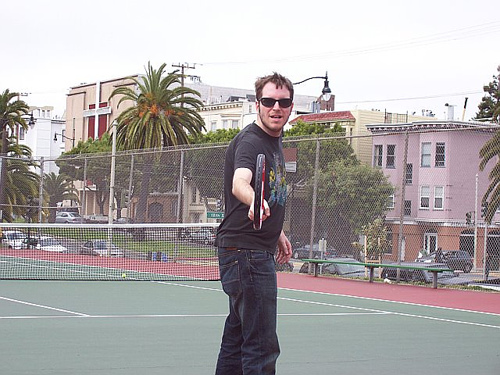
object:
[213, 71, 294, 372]
man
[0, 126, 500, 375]
court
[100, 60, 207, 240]
palm tree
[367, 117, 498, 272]
building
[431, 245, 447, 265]
person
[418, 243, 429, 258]
person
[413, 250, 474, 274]
car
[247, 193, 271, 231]
hand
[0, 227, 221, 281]
net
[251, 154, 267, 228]
racket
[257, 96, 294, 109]
sunglasses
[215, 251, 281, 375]
jean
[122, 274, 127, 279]
ball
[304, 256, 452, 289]
bench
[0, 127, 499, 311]
fence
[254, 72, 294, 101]
hair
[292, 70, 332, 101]
lamp post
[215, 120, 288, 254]
shirt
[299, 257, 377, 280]
car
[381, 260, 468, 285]
truck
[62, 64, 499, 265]
home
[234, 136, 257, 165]
black